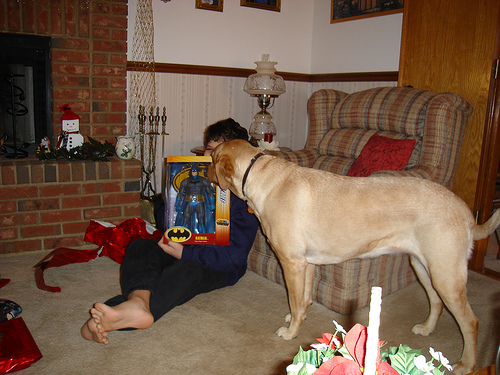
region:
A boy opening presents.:
[16, 22, 281, 374]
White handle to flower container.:
[360, 274, 397, 369]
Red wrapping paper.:
[41, 201, 173, 282]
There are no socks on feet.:
[73, 280, 176, 350]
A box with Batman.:
[158, 145, 237, 250]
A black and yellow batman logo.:
[154, 217, 202, 254]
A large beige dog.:
[202, 122, 482, 374]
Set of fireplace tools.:
[128, 99, 178, 226]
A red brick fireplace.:
[2, 10, 147, 245]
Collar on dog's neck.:
[226, 140, 271, 200]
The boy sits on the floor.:
[50, 106, 295, 356]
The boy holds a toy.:
[148, 117, 269, 277]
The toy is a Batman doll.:
[148, 145, 251, 259]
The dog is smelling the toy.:
[202, 132, 499, 364]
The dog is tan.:
[195, 135, 497, 359]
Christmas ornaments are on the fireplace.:
[16, 97, 128, 169]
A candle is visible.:
[338, 274, 400, 374]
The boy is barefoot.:
[63, 283, 170, 350]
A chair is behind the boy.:
[221, 70, 476, 321]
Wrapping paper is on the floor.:
[24, 197, 169, 304]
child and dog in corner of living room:
[72, 28, 474, 369]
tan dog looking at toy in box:
[181, 120, 481, 366]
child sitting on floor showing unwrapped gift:
[80, 100, 270, 345]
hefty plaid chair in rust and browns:
[250, 70, 460, 310]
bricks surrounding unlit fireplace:
[1, 5, 141, 250]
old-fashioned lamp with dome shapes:
[231, 26, 291, 153]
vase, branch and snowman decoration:
[25, 97, 155, 167]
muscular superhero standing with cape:
[160, 150, 230, 250]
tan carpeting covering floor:
[30, 245, 475, 365]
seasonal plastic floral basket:
[286, 265, 442, 372]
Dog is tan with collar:
[199, 130, 495, 374]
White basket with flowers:
[276, 281, 458, 374]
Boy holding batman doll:
[93, 114, 280, 348]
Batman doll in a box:
[146, 141, 256, 266]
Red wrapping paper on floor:
[11, 210, 191, 304]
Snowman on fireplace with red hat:
[27, 102, 148, 187]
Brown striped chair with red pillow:
[238, 76, 497, 323]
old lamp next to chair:
[241, 41, 302, 186]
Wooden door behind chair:
[382, 15, 497, 321]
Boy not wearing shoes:
[73, 111, 292, 364]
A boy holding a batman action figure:
[76, 117, 256, 343]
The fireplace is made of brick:
[2, 0, 157, 252]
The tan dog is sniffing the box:
[199, 137, 499, 374]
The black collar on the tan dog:
[198, 137, 491, 373]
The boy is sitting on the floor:
[78, 115, 265, 343]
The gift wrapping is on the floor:
[28, 206, 171, 301]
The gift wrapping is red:
[28, 208, 165, 302]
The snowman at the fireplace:
[39, 107, 106, 157]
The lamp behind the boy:
[228, 46, 298, 151]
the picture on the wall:
[325, 0, 407, 29]